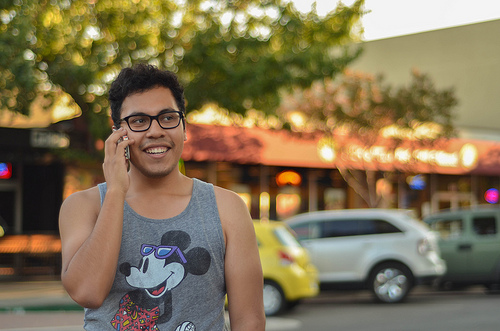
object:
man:
[58, 60, 266, 330]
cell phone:
[112, 130, 134, 163]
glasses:
[116, 110, 191, 133]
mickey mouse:
[110, 229, 213, 331]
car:
[278, 205, 446, 305]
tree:
[0, 2, 367, 151]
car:
[252, 217, 320, 315]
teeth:
[142, 144, 169, 155]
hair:
[101, 56, 192, 127]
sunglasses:
[139, 241, 190, 265]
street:
[0, 284, 499, 330]